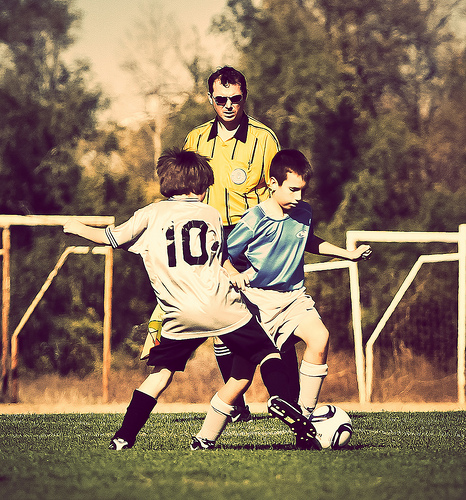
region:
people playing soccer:
[58, 55, 376, 467]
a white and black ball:
[301, 399, 356, 452]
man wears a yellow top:
[174, 60, 285, 188]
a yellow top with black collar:
[186, 115, 276, 184]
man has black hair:
[178, 59, 281, 148]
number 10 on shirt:
[106, 195, 252, 346]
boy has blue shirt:
[231, 146, 380, 332]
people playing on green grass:
[0, 58, 464, 496]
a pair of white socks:
[192, 359, 329, 450]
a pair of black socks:
[116, 354, 295, 452]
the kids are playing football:
[89, 133, 383, 475]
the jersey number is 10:
[135, 199, 242, 299]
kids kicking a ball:
[55, 142, 361, 455]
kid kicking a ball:
[173, 146, 396, 456]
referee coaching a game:
[151, 55, 285, 228]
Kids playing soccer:
[46, 136, 366, 454]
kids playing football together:
[53, 132, 378, 457]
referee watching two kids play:
[176, 59, 292, 216]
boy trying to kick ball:
[48, 136, 383, 462]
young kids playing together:
[54, 140, 376, 461]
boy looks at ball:
[189, 148, 381, 460]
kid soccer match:
[48, 44, 384, 460]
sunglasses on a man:
[207, 92, 244, 103]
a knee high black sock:
[113, 386, 156, 443]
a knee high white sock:
[195, 394, 236, 441]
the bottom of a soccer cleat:
[268, 397, 315, 440]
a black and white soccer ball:
[312, 403, 354, 452]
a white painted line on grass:
[224, 424, 296, 439]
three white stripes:
[212, 342, 233, 357]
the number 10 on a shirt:
[162, 220, 209, 266]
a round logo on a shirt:
[231, 167, 247, 186]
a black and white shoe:
[110, 434, 131, 451]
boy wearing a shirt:
[66, 151, 247, 479]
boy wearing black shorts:
[103, 142, 227, 431]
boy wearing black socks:
[86, 144, 220, 474]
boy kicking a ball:
[52, 149, 211, 450]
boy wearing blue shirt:
[278, 153, 348, 350]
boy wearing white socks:
[273, 143, 342, 383]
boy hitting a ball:
[308, 149, 343, 417]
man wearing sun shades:
[178, 60, 284, 143]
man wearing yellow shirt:
[188, 56, 269, 143]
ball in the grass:
[320, 401, 357, 450]